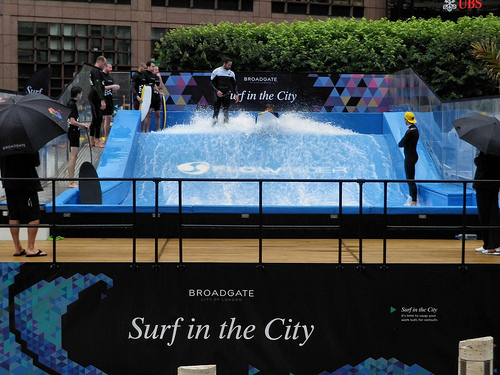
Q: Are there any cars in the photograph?
A: No, there are no cars.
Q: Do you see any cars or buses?
A: No, there are no cars or buses.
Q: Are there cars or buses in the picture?
A: No, there are no cars or buses.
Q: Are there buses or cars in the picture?
A: No, there are no cars or buses.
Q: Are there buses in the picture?
A: No, there are no buses.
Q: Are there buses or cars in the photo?
A: No, there are no buses or cars.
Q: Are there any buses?
A: No, there are no buses.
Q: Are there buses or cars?
A: No, there are no buses or cars.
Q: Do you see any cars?
A: No, there are no cars.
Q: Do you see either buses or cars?
A: No, there are no cars or buses.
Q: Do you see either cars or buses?
A: No, there are no cars or buses.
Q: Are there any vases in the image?
A: No, there are no vases.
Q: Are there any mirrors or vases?
A: No, there are no vases or mirrors.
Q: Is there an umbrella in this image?
A: Yes, there is an umbrella.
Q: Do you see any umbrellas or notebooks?
A: Yes, there is an umbrella.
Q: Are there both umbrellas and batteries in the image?
A: No, there is an umbrella but no batteries.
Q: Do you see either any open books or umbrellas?
A: Yes, there is an open umbrella.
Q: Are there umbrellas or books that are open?
A: Yes, the umbrella is open.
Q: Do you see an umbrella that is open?
A: Yes, there is an open umbrella.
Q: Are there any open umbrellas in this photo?
A: Yes, there is an open umbrella.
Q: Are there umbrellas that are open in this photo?
A: Yes, there is an open umbrella.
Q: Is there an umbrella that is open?
A: Yes, there is an umbrella that is open.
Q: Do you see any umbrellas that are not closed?
A: Yes, there is a open umbrella.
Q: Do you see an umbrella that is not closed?
A: Yes, there is a open umbrella.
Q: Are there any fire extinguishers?
A: No, there are no fire extinguishers.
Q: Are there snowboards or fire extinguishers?
A: No, there are no fire extinguishers or snowboards.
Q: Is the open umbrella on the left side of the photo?
A: Yes, the umbrella is on the left of the image.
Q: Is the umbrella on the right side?
A: No, the umbrella is on the left of the image.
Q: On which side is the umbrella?
A: The umbrella is on the left of the image.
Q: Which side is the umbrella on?
A: The umbrella is on the left of the image.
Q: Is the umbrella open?
A: Yes, the umbrella is open.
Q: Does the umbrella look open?
A: Yes, the umbrella is open.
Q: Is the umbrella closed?
A: No, the umbrella is open.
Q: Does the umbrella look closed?
A: No, the umbrella is open.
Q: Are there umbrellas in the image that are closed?
A: No, there is an umbrella but it is open.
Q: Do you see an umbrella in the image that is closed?
A: No, there is an umbrella but it is open.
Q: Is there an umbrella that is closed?
A: No, there is an umbrella but it is open.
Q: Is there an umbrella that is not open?
A: No, there is an umbrella but it is open.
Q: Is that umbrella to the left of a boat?
A: No, the umbrella is to the left of a person.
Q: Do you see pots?
A: No, there are no pots.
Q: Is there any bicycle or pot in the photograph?
A: No, there are no pots or bicycles.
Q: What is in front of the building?
A: The water is in front of the building.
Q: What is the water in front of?
A: The water is in front of the building.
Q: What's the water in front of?
A: The water is in front of the building.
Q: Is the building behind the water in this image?
A: Yes, the building is behind the water.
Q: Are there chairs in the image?
A: No, there are no chairs.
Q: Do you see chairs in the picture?
A: No, there are no chairs.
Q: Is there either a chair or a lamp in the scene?
A: No, there are no chairs or lamps.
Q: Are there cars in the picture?
A: No, there are no cars.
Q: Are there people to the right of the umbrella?
A: Yes, there is a person to the right of the umbrella.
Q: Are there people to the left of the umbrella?
A: No, the person is to the right of the umbrella.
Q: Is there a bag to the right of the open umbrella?
A: No, there is a person to the right of the umbrella.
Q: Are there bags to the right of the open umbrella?
A: No, there is a person to the right of the umbrella.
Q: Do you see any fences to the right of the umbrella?
A: No, there is a person to the right of the umbrella.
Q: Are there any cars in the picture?
A: No, there are no cars.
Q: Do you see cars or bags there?
A: No, there are no cars or bags.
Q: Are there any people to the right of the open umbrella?
A: Yes, there is a person to the right of the umbrella.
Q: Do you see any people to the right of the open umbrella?
A: Yes, there is a person to the right of the umbrella.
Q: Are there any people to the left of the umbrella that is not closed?
A: No, the person is to the right of the umbrella.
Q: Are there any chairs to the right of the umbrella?
A: No, there is a person to the right of the umbrella.